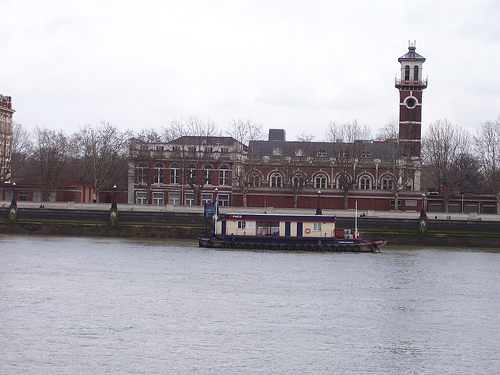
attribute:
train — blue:
[36, 199, 212, 224]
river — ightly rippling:
[14, 221, 483, 366]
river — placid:
[54, 250, 316, 336]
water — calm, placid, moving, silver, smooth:
[3, 223, 498, 375]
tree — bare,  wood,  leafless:
[167, 117, 220, 209]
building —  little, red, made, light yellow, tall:
[117, 35, 428, 236]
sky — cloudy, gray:
[1, 3, 500, 145]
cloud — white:
[214, 40, 309, 83]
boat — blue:
[191, 194, 388, 254]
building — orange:
[12, 150, 94, 215]